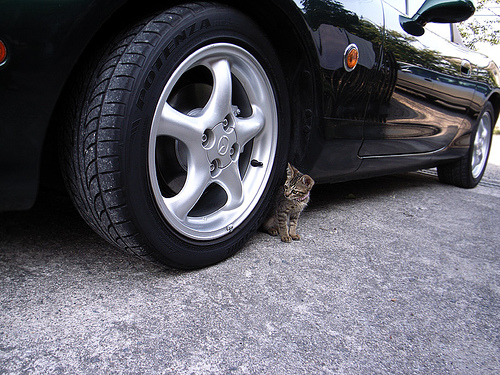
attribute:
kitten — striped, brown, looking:
[258, 163, 316, 244]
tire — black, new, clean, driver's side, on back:
[59, 3, 293, 271]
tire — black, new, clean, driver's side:
[437, 100, 496, 189]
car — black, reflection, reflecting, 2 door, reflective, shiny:
[1, 0, 500, 271]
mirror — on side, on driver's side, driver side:
[399, 0, 476, 37]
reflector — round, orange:
[342, 43, 361, 72]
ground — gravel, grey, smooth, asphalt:
[1, 135, 499, 374]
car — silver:
[395, 60, 492, 117]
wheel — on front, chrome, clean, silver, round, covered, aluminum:
[148, 43, 279, 243]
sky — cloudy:
[457, 0, 500, 69]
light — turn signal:
[0, 39, 9, 67]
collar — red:
[296, 191, 310, 203]